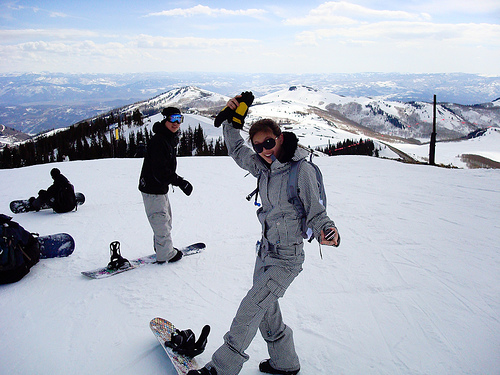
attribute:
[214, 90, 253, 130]
object — yellow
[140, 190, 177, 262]
pants — grey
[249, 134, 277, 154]
goggles — black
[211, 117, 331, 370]
snowsuit — grey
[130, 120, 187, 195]
ski jacket — black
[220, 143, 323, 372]
ski suit — grey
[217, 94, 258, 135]
gloves — black, yellow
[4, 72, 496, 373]
mountains — snow covered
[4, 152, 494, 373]
hill — snowy